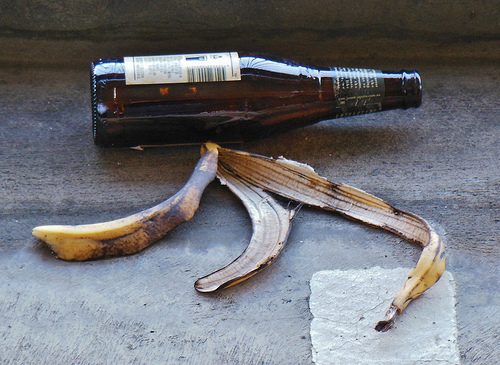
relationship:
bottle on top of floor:
[90, 51, 423, 145] [1, 1, 499, 365]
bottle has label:
[90, 51, 423, 145] [124, 52, 243, 86]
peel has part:
[32, 139, 447, 332] [187, 168, 217, 194]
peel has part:
[32, 139, 447, 332] [32, 216, 141, 239]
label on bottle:
[124, 52, 243, 86] [90, 51, 423, 145]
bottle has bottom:
[90, 51, 423, 145] [89, 61, 99, 145]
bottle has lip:
[90, 51, 423, 145] [413, 70, 423, 110]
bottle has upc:
[90, 51, 423, 145] [186, 66, 227, 81]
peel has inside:
[32, 139, 447, 332] [197, 148, 430, 292]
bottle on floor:
[90, 51, 423, 145] [1, 1, 499, 365]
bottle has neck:
[90, 51, 423, 145] [319, 65, 403, 121]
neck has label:
[319, 65, 403, 121] [330, 65, 387, 118]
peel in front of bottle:
[32, 139, 447, 332] [90, 51, 423, 145]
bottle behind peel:
[90, 51, 423, 145] [32, 139, 447, 332]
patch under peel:
[308, 265, 461, 364] [32, 139, 447, 332]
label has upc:
[124, 52, 243, 86] [186, 66, 227, 81]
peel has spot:
[32, 139, 447, 332] [187, 168, 217, 194]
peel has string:
[32, 139, 447, 332] [285, 199, 294, 209]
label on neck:
[330, 65, 387, 118] [319, 65, 403, 121]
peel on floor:
[32, 139, 447, 332] [1, 1, 499, 365]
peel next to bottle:
[32, 139, 447, 332] [90, 51, 423, 145]